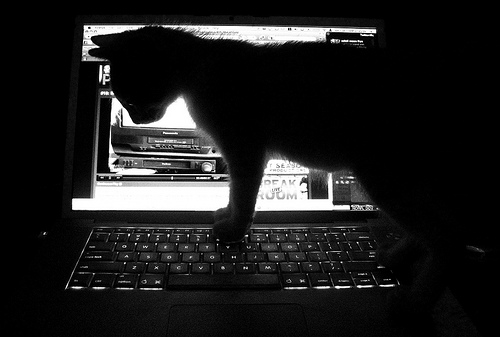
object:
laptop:
[46, 16, 424, 330]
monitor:
[64, 10, 398, 223]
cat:
[87, 19, 498, 248]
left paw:
[211, 215, 254, 239]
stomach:
[267, 142, 359, 177]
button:
[346, 250, 380, 262]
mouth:
[128, 110, 164, 125]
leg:
[214, 144, 266, 237]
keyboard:
[64, 220, 404, 300]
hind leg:
[351, 172, 471, 298]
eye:
[124, 101, 137, 107]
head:
[85, 19, 186, 127]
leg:
[383, 171, 447, 262]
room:
[2, 2, 500, 335]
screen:
[67, 14, 393, 223]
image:
[3, 2, 498, 336]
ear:
[86, 48, 106, 59]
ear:
[90, 34, 113, 48]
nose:
[128, 118, 142, 126]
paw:
[209, 202, 234, 220]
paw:
[371, 243, 408, 270]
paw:
[400, 273, 439, 304]